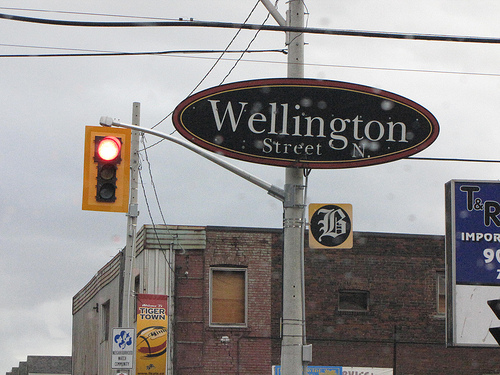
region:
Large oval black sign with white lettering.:
[163, 76, 446, 167]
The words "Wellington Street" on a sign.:
[195, 90, 421, 159]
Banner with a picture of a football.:
[125, 286, 180, 373]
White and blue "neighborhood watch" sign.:
[106, 322, 136, 374]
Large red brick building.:
[171, 233, 444, 366]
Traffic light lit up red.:
[77, 115, 136, 222]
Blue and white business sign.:
[438, 172, 498, 362]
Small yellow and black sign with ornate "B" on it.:
[299, 196, 359, 253]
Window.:
[201, 255, 252, 340]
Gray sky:
[11, 120, 73, 317]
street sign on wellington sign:
[170, 77, 441, 170]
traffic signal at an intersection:
[78, 117, 131, 216]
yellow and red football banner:
[130, 289, 173, 374]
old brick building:
[71, 216, 495, 373]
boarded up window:
[205, 262, 251, 332]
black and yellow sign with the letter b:
[301, 202, 358, 252]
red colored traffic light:
[95, 133, 124, 164]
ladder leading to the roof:
[172, 235, 202, 373]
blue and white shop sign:
[444, 179, 499, 348]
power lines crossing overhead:
[0, 3, 499, 84]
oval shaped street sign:
[170, 62, 440, 191]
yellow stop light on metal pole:
[81, 125, 136, 225]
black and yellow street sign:
[300, 191, 367, 265]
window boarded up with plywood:
[186, 225, 276, 345]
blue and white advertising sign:
[433, 168, 498, 344]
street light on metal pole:
[93, 106, 360, 373]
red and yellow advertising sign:
[132, 290, 187, 373]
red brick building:
[155, 222, 472, 372]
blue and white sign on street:
[108, 324, 137, 373]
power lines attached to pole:
[16, 6, 496, 78]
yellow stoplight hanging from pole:
[62, 98, 149, 224]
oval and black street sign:
[162, 66, 452, 178]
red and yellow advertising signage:
[132, 286, 170, 371]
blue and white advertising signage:
[432, 178, 495, 374]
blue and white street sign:
[108, 326, 138, 374]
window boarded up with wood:
[202, 249, 264, 343]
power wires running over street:
[23, 1, 485, 95]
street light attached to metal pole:
[99, 32, 405, 369]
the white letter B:
[311, 194, 357, 249]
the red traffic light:
[89, 124, 132, 169]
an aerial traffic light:
[66, 102, 157, 259]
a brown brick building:
[18, 190, 482, 374]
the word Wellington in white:
[207, 84, 414, 147]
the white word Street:
[248, 127, 327, 167]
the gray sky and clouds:
[0, 198, 52, 290]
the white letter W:
[208, 88, 248, 139]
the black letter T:
[451, 173, 483, 214]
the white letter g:
[323, 107, 352, 154]